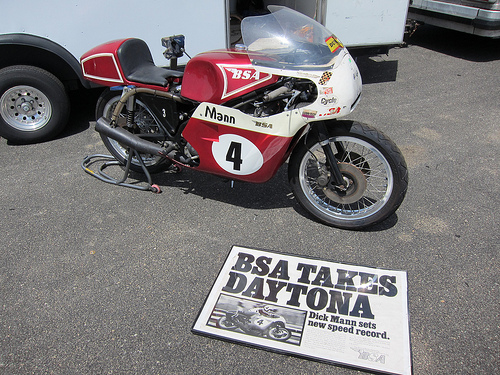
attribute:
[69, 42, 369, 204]
motorcycle — red, white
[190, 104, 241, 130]
decal — mann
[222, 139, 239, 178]
4 — number, black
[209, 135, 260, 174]
oval — white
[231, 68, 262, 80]
bsa — initials, design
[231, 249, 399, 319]
headline — bsa takes daytona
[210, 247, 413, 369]
page — framed, news, headline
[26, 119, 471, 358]
ground — asphalt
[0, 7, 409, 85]
trailer — parked, white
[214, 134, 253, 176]
circle — white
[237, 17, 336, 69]
windshield — window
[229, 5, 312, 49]
door — open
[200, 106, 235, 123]
mann — written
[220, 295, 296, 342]
picture — motorcycle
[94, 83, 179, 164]
tire — back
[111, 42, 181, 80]
seat — black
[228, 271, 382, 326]
daytona — word